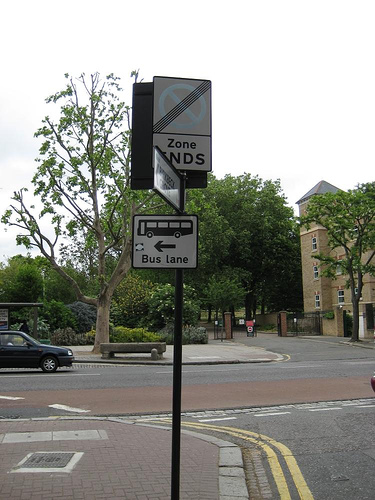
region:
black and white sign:
[130, 213, 200, 270]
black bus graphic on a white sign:
[129, 211, 196, 268]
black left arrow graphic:
[153, 238, 177, 253]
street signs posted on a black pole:
[128, 75, 213, 499]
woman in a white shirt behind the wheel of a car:
[0, 329, 76, 373]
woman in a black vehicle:
[1, 329, 74, 372]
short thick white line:
[41, 401, 90, 413]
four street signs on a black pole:
[128, 76, 214, 499]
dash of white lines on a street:
[194, 402, 374, 428]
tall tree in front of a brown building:
[293, 179, 373, 344]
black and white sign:
[122, 213, 202, 275]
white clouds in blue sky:
[314, 52, 357, 87]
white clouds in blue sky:
[241, 85, 268, 107]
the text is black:
[132, 213, 196, 275]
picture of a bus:
[118, 212, 197, 243]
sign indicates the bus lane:
[129, 215, 201, 269]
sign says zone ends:
[153, 73, 216, 158]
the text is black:
[154, 82, 215, 174]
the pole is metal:
[164, 265, 182, 495]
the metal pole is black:
[173, 269, 180, 494]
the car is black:
[0, 323, 75, 371]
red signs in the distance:
[242, 317, 255, 331]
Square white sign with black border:
[133, 215, 196, 270]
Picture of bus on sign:
[135, 219, 192, 235]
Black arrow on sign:
[153, 240, 176, 252]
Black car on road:
[0, 329, 73, 373]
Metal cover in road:
[24, 451, 76, 467]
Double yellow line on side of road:
[159, 412, 317, 497]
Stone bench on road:
[96, 340, 176, 358]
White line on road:
[47, 400, 101, 416]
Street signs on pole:
[110, 75, 202, 495]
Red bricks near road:
[108, 441, 158, 494]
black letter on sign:
[163, 136, 179, 148]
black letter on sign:
[174, 139, 183, 150]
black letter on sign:
[181, 136, 191, 150]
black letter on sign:
[189, 139, 199, 150]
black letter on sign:
[167, 149, 182, 166]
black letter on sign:
[179, 150, 195, 167]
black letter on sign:
[192, 151, 208, 166]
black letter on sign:
[138, 251, 149, 264]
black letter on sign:
[147, 254, 156, 264]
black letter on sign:
[155, 253, 164, 265]